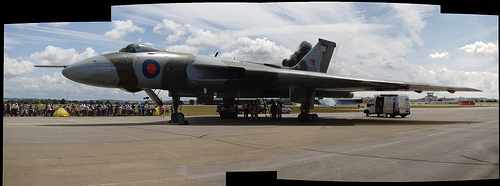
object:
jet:
[32, 34, 484, 125]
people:
[0, 101, 162, 117]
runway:
[0, 122, 496, 166]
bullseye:
[137, 58, 167, 80]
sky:
[111, 6, 433, 38]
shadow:
[32, 116, 486, 127]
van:
[360, 93, 419, 118]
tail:
[278, 34, 352, 74]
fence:
[0, 115, 168, 119]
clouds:
[118, 1, 488, 57]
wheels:
[164, 112, 193, 123]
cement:
[1, 126, 499, 170]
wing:
[242, 67, 484, 93]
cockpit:
[115, 43, 164, 54]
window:
[119, 43, 142, 52]